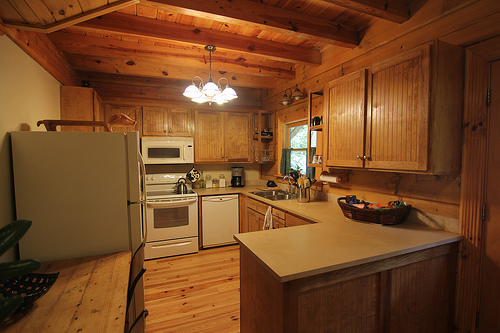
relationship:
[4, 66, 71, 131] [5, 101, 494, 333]
wall on building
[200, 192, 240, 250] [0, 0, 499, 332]
dishwasher standing inside building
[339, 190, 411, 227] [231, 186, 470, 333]
basket sitting on top of counter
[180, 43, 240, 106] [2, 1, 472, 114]
chandelier hanging from ceiling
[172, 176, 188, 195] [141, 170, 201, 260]
tea kettle sitting on top of stove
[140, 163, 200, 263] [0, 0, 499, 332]
stove sitting inside building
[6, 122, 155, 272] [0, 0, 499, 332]
refrigerator in corner of building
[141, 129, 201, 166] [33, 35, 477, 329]
microwave inside of kitchen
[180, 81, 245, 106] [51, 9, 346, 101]
light attached to ceiling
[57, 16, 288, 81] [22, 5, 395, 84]
wood attached to ceiling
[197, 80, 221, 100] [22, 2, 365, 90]
light are attached to ceiling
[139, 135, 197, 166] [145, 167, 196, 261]
microwave above range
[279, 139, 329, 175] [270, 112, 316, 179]
curtain attached to window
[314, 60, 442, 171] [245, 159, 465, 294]
cabinets are hanging above counter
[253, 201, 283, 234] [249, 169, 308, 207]
towel hanging below sink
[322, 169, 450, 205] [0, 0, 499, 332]
panels are hanging inside building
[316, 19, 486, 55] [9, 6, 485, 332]
panels are hanging inside room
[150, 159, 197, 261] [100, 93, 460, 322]
stove in kitchen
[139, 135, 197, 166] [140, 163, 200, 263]
microwave above stove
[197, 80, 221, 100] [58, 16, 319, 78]
light hanging from beam